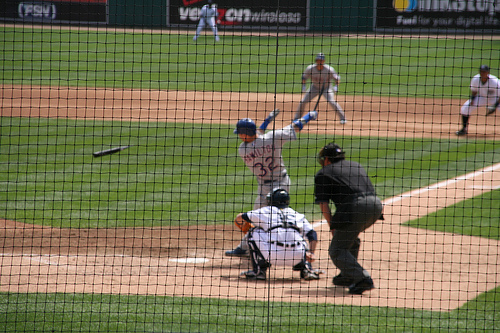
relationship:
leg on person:
[324, 89, 349, 125] [293, 52, 349, 126]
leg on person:
[288, 89, 317, 120] [293, 52, 349, 126]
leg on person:
[457, 97, 478, 135] [456, 57, 496, 140]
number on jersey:
[252, 154, 277, 176] [238, 124, 294, 177]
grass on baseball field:
[401, 186, 498, 243] [2, 2, 497, 330]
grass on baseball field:
[4, 28, 498, 99] [2, 2, 497, 330]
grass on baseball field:
[4, 116, 496, 227] [2, 2, 497, 330]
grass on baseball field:
[4, 282, 498, 330] [2, 2, 497, 330]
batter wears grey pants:
[234, 109, 318, 210] [255, 173, 289, 203]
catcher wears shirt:
[231, 186, 326, 287] [248, 206, 310, 251]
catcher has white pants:
[234, 187, 319, 280] [244, 229, 324, 275]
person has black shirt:
[307, 142, 389, 295] [306, 154, 377, 202]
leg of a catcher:
[301, 252, 321, 280] [234, 187, 319, 280]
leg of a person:
[241, 170, 351, 257] [287, 129, 421, 331]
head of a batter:
[232, 117, 256, 141] [234, 109, 318, 210]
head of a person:
[317, 142, 346, 163] [455, 65, 490, 135]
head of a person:
[264, 185, 290, 206] [294, 52, 346, 123]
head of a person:
[313, 53, 325, 67] [312, 140, 384, 295]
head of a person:
[477, 66, 490, 77] [235, 187, 319, 279]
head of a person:
[317, 142, 349, 162] [312, 140, 384, 295]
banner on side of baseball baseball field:
[166, 0, 311, 31] [0, 0, 499, 333]